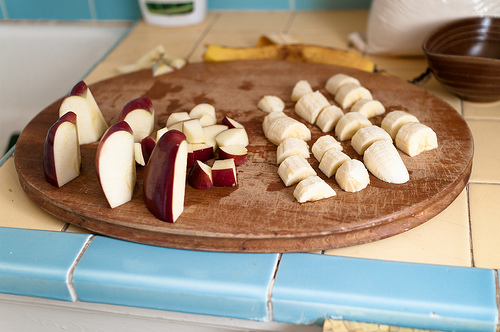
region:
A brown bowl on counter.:
[421, 15, 499, 102]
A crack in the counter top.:
[264, 250, 286, 317]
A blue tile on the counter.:
[268, 252, 498, 327]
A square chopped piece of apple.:
[209, 156, 240, 188]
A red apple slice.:
[41, 109, 84, 188]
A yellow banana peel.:
[196, 29, 381, 71]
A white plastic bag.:
[350, 0, 498, 56]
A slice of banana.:
[288, 173, 335, 203]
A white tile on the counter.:
[467, 179, 499, 264]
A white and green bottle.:
[140, 0, 207, 26]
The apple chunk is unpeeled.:
[53, 80, 114, 148]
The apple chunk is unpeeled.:
[29, 109, 94, 192]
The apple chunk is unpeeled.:
[113, 93, 158, 144]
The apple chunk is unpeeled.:
[90, 118, 145, 215]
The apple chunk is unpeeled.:
[138, 125, 192, 228]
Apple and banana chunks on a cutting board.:
[10, 52, 475, 264]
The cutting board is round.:
[8, 48, 485, 264]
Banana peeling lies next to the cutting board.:
[13, 15, 480, 255]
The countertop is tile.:
[1, 0, 498, 327]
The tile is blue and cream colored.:
[0, 0, 499, 330]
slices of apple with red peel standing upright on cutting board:
[42, 73, 194, 219]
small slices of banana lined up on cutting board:
[260, 68, 438, 202]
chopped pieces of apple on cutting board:
[133, 93, 248, 204]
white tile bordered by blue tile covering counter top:
[3, 0, 494, 318]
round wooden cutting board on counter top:
[8, 53, 478, 257]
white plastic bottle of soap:
[134, 0, 214, 33]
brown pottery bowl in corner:
[411, 13, 499, 105]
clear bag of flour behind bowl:
[358, 1, 498, 57]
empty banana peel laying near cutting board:
[200, 25, 392, 76]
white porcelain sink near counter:
[2, 9, 145, 160]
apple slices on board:
[57, 87, 243, 214]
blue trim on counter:
[28, 268, 498, 329]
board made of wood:
[203, 205, 458, 238]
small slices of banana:
[285, 83, 447, 203]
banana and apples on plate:
[55, 84, 435, 204]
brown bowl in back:
[435, 32, 498, 100]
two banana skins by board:
[214, 43, 375, 76]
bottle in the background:
[130, 0, 225, 35]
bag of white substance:
[374, 4, 437, 56]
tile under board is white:
[433, 203, 493, 259]